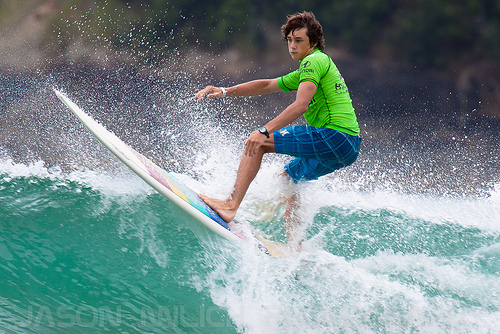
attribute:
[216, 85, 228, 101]
band — white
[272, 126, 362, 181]
shorts — blue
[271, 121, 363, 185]
shorts — blue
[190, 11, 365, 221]
male — teen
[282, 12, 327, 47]
hair — brown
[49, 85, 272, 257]
surfboard — white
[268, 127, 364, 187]
shorts — blue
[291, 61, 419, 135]
shirt — green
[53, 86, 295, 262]
surf board — White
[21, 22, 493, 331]
water — splashed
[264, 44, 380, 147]
shirt — green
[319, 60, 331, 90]
stitching — black